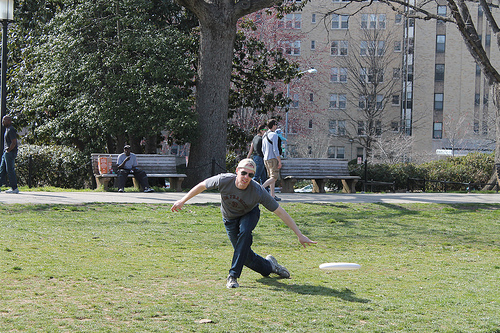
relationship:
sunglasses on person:
[237, 167, 258, 177] [168, 157, 320, 289]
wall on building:
[445, 62, 474, 127] [304, 22, 399, 139]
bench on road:
[90, 151, 187, 188] [1, 185, 498, 205]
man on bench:
[116, 146, 141, 192] [91, 141, 187, 188]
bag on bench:
[98, 155, 111, 172] [90, 151, 187, 188]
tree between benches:
[181, 12, 237, 161] [73, 137, 360, 197]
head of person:
[230, 152, 260, 191] [172, 155, 320, 292]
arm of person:
[262, 194, 322, 248] [172, 155, 320, 292]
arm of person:
[181, 172, 223, 203] [172, 155, 320, 292]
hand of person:
[297, 234, 318, 249] [172, 155, 320, 292]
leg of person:
[224, 217, 291, 287] [172, 155, 320, 292]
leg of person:
[228, 205, 259, 278] [257, 117, 285, 194]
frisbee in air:
[314, 256, 364, 275] [301, 242, 377, 292]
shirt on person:
[199, 167, 281, 224] [168, 157, 320, 289]